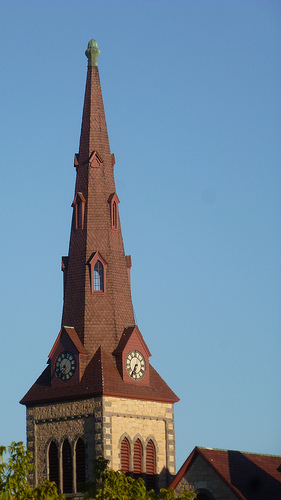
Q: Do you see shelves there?
A: No, there are no shelves.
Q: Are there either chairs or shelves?
A: No, there are no shelves or chairs.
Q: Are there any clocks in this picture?
A: Yes, there is a clock.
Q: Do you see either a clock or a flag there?
A: Yes, there is a clock.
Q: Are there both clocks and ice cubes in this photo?
A: No, there is a clock but no ice cubes.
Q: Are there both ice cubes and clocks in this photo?
A: No, there is a clock but no ice cubes.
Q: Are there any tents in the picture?
A: No, there are no tents.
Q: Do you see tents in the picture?
A: No, there are no tents.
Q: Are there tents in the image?
A: No, there are no tents.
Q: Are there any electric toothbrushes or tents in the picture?
A: No, there are no tents or electric toothbrushes.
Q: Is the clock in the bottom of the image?
A: Yes, the clock is in the bottom of the image.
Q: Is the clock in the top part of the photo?
A: No, the clock is in the bottom of the image.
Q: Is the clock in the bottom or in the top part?
A: The clock is in the bottom of the image.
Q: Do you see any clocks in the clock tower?
A: Yes, there is a clock in the clock tower.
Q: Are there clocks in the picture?
A: Yes, there is a clock.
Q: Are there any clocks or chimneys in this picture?
A: Yes, there is a clock.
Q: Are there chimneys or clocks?
A: Yes, there is a clock.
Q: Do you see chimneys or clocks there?
A: Yes, there is a clock.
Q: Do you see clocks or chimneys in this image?
A: Yes, there is a clock.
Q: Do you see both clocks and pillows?
A: No, there is a clock but no pillows.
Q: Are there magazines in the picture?
A: No, there are no magazines.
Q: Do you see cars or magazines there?
A: No, there are no magazines or cars.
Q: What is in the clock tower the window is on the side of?
A: The clock is in the clock tower.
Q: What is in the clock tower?
A: The clock is in the clock tower.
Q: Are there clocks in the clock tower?
A: Yes, there is a clock in the clock tower.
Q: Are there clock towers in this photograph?
A: Yes, there is a clock tower.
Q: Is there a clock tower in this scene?
A: Yes, there is a clock tower.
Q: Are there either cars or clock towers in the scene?
A: Yes, there is a clock tower.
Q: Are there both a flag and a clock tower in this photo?
A: No, there is a clock tower but no flags.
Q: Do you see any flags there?
A: No, there are no flags.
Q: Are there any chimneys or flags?
A: No, there are no flags or chimneys.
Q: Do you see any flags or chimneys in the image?
A: No, there are no flags or chimneys.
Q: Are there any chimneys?
A: No, there are no chimneys.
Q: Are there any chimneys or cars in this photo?
A: No, there are no chimneys or cars.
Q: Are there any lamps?
A: No, there are no lamps.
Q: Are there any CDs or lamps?
A: No, there are no lamps or cds.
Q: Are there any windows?
A: Yes, there is a window.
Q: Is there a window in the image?
A: Yes, there is a window.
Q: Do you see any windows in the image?
A: Yes, there is a window.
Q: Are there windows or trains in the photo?
A: Yes, there is a window.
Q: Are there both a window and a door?
A: No, there is a window but no doors.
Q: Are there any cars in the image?
A: No, there are no cars.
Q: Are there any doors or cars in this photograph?
A: No, there are no cars or doors.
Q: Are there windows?
A: Yes, there is a window.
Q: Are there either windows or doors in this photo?
A: Yes, there is a window.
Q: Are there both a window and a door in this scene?
A: No, there is a window but no doors.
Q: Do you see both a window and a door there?
A: No, there is a window but no doors.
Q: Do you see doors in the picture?
A: No, there are no doors.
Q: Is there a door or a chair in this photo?
A: No, there are no doors or chairs.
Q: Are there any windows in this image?
A: Yes, there is a window.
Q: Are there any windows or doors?
A: Yes, there is a window.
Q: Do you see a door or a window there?
A: Yes, there is a window.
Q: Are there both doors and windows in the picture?
A: No, there is a window but no doors.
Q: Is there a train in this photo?
A: No, there are no trains.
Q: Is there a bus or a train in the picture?
A: No, there are no trains or buses.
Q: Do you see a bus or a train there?
A: No, there are no trains or buses.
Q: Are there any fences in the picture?
A: No, there are no fences.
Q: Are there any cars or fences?
A: No, there are no fences or cars.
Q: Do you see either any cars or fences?
A: No, there are no fences or cars.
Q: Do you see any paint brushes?
A: No, there are no paint brushes.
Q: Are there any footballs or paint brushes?
A: No, there are no paint brushes or footballs.